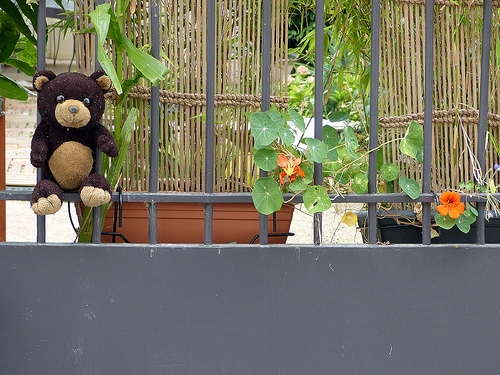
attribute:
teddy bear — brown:
[29, 69, 121, 218]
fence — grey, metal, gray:
[0, 0, 499, 243]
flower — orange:
[439, 191, 465, 220]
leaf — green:
[249, 109, 280, 145]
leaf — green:
[254, 149, 280, 174]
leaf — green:
[252, 178, 284, 214]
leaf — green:
[304, 137, 330, 164]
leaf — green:
[303, 185, 332, 211]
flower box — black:
[378, 206, 499, 245]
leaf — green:
[0, 75, 30, 102]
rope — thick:
[114, 78, 290, 108]